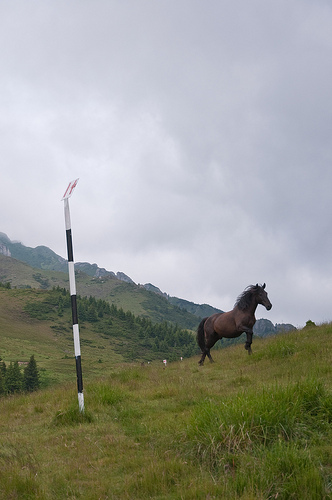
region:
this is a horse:
[147, 266, 293, 361]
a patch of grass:
[191, 409, 250, 462]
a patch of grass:
[202, 424, 266, 479]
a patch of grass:
[136, 377, 228, 465]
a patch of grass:
[248, 439, 297, 491]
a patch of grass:
[18, 384, 86, 462]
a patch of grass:
[234, 387, 311, 433]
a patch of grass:
[156, 444, 222, 490]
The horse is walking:
[193, 277, 276, 364]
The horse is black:
[195, 278, 273, 367]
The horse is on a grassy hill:
[188, 281, 272, 372]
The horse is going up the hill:
[189, 280, 276, 366]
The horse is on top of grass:
[190, 279, 276, 368]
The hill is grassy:
[15, 316, 329, 499]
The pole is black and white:
[57, 197, 93, 415]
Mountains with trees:
[4, 236, 271, 368]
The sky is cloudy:
[22, 31, 319, 280]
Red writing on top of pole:
[57, 179, 82, 202]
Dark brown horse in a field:
[177, 251, 270, 363]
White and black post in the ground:
[38, 172, 99, 462]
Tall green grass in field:
[5, 448, 43, 499]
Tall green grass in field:
[46, 397, 91, 428]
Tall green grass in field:
[176, 394, 253, 448]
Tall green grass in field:
[258, 370, 326, 454]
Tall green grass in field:
[255, 343, 313, 370]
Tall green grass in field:
[115, 355, 151, 383]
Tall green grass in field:
[102, 364, 149, 408]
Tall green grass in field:
[8, 384, 60, 407]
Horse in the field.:
[184, 240, 331, 406]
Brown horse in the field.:
[163, 271, 285, 372]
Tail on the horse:
[186, 305, 222, 351]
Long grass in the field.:
[126, 350, 324, 465]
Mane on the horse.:
[238, 273, 263, 319]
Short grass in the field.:
[88, 407, 178, 470]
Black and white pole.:
[46, 193, 166, 444]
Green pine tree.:
[13, 341, 39, 398]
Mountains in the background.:
[98, 246, 251, 413]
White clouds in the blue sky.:
[159, 145, 263, 264]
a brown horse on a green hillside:
[171, 278, 295, 403]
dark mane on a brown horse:
[231, 280, 274, 313]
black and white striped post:
[56, 171, 93, 419]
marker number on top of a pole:
[58, 176, 90, 422]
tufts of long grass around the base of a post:
[51, 404, 100, 432]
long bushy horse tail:
[194, 316, 210, 353]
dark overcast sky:
[2, 197, 331, 327]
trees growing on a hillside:
[46, 282, 204, 355]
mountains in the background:
[2, 230, 301, 338]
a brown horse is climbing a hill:
[192, 278, 275, 370]